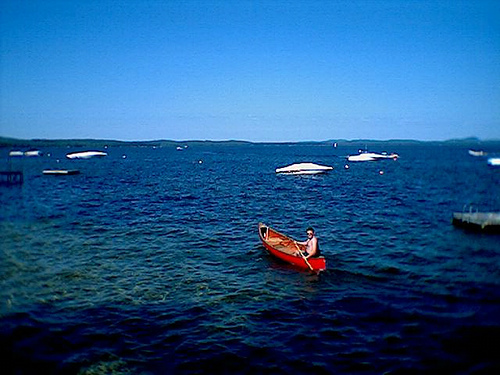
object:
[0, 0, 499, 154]
distance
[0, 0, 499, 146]
blue sky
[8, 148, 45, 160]
boats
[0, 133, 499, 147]
land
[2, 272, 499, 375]
shadow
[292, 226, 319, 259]
man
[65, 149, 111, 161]
boat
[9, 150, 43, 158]
boat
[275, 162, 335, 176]
boat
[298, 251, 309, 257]
bathing suit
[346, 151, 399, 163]
boat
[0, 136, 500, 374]
water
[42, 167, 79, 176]
flat dock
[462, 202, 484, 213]
silver handles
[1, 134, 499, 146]
shore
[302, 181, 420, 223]
waves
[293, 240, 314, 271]
paddle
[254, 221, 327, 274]
boat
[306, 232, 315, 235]
sunglasses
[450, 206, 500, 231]
dock